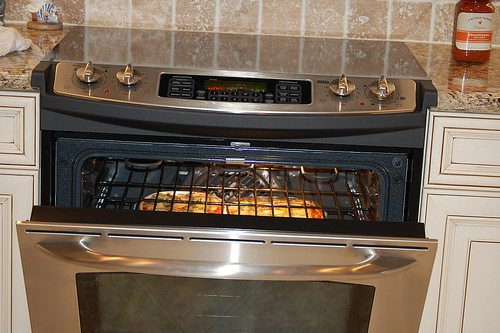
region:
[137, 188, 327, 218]
baked dish in an oven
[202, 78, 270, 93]
red and green text on a digital display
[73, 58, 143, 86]
two silver stove knobs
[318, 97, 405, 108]
three red stove lights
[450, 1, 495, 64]
red sauce in a jar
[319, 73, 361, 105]
black numbers surrounding a silver knob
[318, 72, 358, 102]
silver knob and small red light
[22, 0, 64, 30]
brown white and blue decoration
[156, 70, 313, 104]
black oven panel with a digital screen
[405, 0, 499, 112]
red sauce jar on a brown marble counter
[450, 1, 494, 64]
clear jar with white and red label and orange-red sauce in it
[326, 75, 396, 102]
two brass looking stove knobs on the right of the stove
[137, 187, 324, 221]
food baking in an oven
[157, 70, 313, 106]
fancy controls for an oven or stove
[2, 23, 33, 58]
white rumpled piece of hand towel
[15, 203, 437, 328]
open oven door with large window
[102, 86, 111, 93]
small red light on the left of the stove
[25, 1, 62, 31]
undistinguishable ceramic figurine with wooden base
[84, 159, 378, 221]
oven rack not being used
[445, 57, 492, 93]
reflection of a jar of sauce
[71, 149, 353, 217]
food in the oven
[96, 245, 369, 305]
handle to the oven door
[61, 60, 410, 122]
knobs on the oven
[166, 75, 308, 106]
display screen for settings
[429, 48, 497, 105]
counter next to oven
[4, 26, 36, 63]
counter next to oven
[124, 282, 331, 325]
area to see dish in oven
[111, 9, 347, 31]
wall behind the oven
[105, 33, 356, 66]
surface of the oven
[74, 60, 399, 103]
silver knobs on a stove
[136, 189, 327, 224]
food cooking inside an oven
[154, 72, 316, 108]
digital display on a stove top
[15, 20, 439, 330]
a stainless steel oven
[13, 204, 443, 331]
stainless steel oven door that is open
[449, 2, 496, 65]
bottle of pasta sauce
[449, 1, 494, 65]
bottle of pasta sauce from Target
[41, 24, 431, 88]
very clean stove top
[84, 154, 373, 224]
food cooking in a convection oven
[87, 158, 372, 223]
oven rack inside an oven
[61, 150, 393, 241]
this is an oven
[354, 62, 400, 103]
this is a knob on the oven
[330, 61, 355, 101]
this is a knob on the oven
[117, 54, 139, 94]
this is a knob on the oven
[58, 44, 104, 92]
this is a knob on the oven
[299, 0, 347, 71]
this is a a tile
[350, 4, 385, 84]
this is a a tile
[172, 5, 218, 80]
this is a a tile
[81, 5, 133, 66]
this is a a tile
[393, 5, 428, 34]
this is a a tile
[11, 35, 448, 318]
food cooking in an oven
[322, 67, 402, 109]
two knobs on a stovetop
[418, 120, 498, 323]
white kitchen cabinets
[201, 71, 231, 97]
stove has numbers on it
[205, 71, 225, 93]
numbers on stove are red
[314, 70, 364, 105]
stove has knobs on it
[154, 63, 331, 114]
oven has buttons on it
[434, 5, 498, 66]
jar on top of counter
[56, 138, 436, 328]
oven door is part way open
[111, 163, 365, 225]
rack inside of the oven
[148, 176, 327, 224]
food inside of the oven